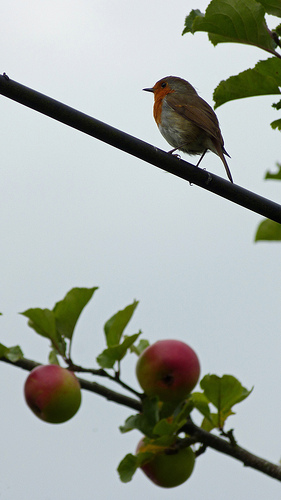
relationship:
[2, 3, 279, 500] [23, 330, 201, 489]
tree has apples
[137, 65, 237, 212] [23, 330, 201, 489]
bird above apples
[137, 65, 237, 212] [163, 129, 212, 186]
bird has legs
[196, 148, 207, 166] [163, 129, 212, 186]
legs bird legs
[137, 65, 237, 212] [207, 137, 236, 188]
bird has tail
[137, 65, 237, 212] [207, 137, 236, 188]
bird tail tail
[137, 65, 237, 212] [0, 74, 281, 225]
bird on branch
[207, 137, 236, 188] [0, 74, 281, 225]
tail touching branch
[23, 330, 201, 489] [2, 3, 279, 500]
apples on tree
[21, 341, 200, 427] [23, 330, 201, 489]
red hued apples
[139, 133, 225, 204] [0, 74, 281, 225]
claw on branch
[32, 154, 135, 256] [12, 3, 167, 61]
powder blue sky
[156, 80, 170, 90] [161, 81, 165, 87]
bird's eye bird's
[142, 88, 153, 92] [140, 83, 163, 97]
beak colored beak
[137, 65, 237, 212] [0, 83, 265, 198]
bird on a branch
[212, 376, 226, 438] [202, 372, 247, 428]
vein running down leaf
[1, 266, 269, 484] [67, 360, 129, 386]
leaves growing on twigs